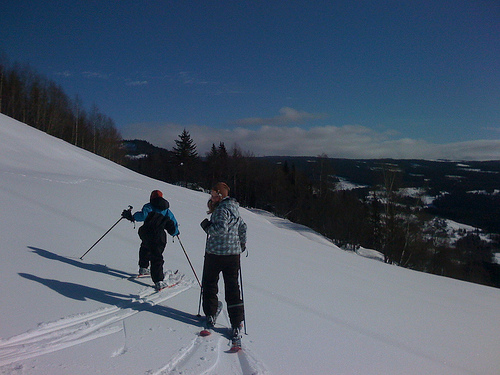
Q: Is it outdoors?
A: Yes, it is outdoors.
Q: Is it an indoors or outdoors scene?
A: It is outdoors.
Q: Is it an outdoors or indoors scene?
A: It is outdoors.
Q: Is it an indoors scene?
A: No, it is outdoors.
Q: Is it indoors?
A: No, it is outdoors.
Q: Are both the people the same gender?
A: No, they are both male and female.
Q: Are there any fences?
A: No, there are no fences.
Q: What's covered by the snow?
A: The ground is covered by the snow.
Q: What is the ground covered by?
A: The ground is covered by the snow.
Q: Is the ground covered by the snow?
A: Yes, the ground is covered by the snow.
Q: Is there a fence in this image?
A: No, there are no fences.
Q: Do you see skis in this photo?
A: Yes, there are skis.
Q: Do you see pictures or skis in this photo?
A: Yes, there are skis.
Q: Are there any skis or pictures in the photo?
A: Yes, there are skis.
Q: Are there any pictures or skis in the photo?
A: Yes, there are skis.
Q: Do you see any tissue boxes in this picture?
A: No, there are no tissue boxes.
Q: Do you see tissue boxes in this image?
A: No, there are no tissue boxes.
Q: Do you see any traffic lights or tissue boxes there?
A: No, there are no tissue boxes or traffic lights.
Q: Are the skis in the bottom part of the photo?
A: Yes, the skis are in the bottom of the image.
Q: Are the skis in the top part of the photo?
A: No, the skis are in the bottom of the image.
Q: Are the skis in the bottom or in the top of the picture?
A: The skis are in the bottom of the image.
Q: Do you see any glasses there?
A: No, there are no glasses.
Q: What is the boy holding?
A: The boy is holding the pole.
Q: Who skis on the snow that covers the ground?
A: The boy skis on the snow.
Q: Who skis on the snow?
A: The boy skis on the snow.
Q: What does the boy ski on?
A: The boy skis on the snow.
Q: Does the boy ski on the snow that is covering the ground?
A: Yes, the boy skis on the snow.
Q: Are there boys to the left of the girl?
A: Yes, there is a boy to the left of the girl.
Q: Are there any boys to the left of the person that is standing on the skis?
A: Yes, there is a boy to the left of the girl.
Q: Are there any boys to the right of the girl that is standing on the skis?
A: No, the boy is to the left of the girl.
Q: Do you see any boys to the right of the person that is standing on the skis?
A: No, the boy is to the left of the girl.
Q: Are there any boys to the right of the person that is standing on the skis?
A: No, the boy is to the left of the girl.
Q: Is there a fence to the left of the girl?
A: No, there is a boy to the left of the girl.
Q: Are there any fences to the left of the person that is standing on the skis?
A: No, there is a boy to the left of the girl.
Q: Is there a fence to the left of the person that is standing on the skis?
A: No, there is a boy to the left of the girl.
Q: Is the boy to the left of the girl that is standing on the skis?
A: Yes, the boy is to the left of the girl.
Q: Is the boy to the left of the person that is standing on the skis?
A: Yes, the boy is to the left of the girl.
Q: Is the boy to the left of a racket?
A: No, the boy is to the left of the girl.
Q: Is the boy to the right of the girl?
A: No, the boy is to the left of the girl.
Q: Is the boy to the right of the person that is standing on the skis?
A: No, the boy is to the left of the girl.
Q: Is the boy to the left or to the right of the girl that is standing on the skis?
A: The boy is to the left of the girl.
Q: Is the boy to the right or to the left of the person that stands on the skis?
A: The boy is to the left of the girl.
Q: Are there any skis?
A: Yes, there are skis.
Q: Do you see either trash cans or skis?
A: Yes, there are skis.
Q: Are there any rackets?
A: No, there are no rackets.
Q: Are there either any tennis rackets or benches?
A: No, there are no tennis rackets or benches.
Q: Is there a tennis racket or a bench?
A: No, there are no rackets or benches.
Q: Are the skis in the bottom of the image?
A: Yes, the skis are in the bottom of the image.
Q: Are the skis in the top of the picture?
A: No, the skis are in the bottom of the image.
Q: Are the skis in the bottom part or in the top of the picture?
A: The skis are in the bottom of the image.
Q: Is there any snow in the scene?
A: Yes, there is snow.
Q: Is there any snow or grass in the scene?
A: Yes, there is snow.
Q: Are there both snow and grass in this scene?
A: No, there is snow but no grass.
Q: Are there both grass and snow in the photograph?
A: No, there is snow but no grass.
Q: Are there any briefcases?
A: No, there are no briefcases.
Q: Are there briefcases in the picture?
A: No, there are no briefcases.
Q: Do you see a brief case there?
A: No, there are no briefcases.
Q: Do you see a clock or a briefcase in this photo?
A: No, there are no briefcases or clocks.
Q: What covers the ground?
A: The snow covers the ground.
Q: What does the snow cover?
A: The snow covers the ground.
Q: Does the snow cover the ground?
A: Yes, the snow covers the ground.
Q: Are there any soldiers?
A: No, there are no soldiers.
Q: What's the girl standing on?
A: The girl is standing on the skis.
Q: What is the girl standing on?
A: The girl is standing on the skis.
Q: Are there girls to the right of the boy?
A: Yes, there is a girl to the right of the boy.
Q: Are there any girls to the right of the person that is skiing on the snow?
A: Yes, there is a girl to the right of the boy.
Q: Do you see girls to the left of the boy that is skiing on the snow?
A: No, the girl is to the right of the boy.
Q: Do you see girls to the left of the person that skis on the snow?
A: No, the girl is to the right of the boy.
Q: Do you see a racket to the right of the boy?
A: No, there is a girl to the right of the boy.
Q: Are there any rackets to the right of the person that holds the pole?
A: No, there is a girl to the right of the boy.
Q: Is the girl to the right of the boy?
A: Yes, the girl is to the right of the boy.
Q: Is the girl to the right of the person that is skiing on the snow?
A: Yes, the girl is to the right of the boy.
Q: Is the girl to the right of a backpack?
A: No, the girl is to the right of the boy.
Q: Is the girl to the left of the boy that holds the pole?
A: No, the girl is to the right of the boy.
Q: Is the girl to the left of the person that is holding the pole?
A: No, the girl is to the right of the boy.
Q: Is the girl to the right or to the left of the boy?
A: The girl is to the right of the boy.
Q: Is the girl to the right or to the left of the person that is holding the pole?
A: The girl is to the right of the boy.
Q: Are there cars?
A: No, there are no cars.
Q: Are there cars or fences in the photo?
A: No, there are no cars or fences.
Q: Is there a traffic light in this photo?
A: No, there are no traffic lights.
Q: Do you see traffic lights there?
A: No, there are no traffic lights.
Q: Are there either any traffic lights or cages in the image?
A: No, there are no traffic lights or cages.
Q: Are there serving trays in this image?
A: No, there are no serving trays.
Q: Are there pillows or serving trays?
A: No, there are no serving trays or pillows.